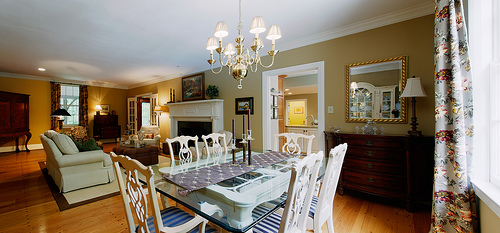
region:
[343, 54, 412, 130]
A large gold framed mirror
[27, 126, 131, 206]
A cream colored sofa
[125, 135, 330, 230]
A glass top table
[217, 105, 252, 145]
Long brown candlesticks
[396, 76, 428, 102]
A white lampshade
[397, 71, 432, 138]
A table lamp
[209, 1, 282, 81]
A chandelier hanging from the ceiling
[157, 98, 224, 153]
A white fireplace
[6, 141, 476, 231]
Hardwood floors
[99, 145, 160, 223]
This is a chair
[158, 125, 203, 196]
This is a chair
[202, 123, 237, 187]
This is a chair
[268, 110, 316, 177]
This is a chair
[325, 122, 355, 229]
This is a chair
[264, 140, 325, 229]
This is a chair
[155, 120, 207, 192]
This is a chair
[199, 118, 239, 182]
This is a chair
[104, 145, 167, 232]
This is a chair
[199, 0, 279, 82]
chandelier hanging from the ceiling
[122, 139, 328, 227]
glass table in a dining room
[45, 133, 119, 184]
white sofa in front of a coffee table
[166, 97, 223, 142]
white fire place in the living room area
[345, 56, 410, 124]
gold framed mirror on the wall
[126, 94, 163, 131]
window shutters are open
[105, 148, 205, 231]
light brown chair with blue striped cushion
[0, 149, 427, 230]
hardwood flooring on the ground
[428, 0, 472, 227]
floral curtains on the window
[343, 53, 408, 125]
a golden frame mirror on the wall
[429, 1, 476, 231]
flowery curtains on the window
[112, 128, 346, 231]
a glass table with six white chairs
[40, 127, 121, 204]
a gray couch in a living room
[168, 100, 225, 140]
a white fireplace in a living room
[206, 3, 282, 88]
a golden chandelier hanging from the ceiling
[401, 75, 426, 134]
a white lampshade on a wooden base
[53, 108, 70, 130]
a black lamp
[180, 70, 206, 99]
a framed painting above a fireplace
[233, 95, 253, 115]
a black framed painting on the wall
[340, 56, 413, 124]
a mirror on a wall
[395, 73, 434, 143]
a lamp on a dresser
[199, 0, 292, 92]
a chandelier hanging from a ceiling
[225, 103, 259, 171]
three candles on a table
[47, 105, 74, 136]
a lamp at the end of a couch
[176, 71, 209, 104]
a picture in a frame on a wall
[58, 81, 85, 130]
a window of a room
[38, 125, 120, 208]
a white couch in a room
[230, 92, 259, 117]
a picture in a frame on a wall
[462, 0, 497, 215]
a window in a room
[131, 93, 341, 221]
table in the room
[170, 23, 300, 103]
object above the table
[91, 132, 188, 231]
back of a chair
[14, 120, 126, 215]
sofa in the room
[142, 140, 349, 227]
glass dinner table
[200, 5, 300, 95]
bronze hanging chandelier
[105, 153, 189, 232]
white dinner chair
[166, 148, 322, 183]
floral runner on table top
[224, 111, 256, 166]
brown candlesticks on table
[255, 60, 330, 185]
white wooden door frame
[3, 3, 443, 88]
white painted ceiling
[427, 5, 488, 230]
blue floral curtain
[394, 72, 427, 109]
white lampshade